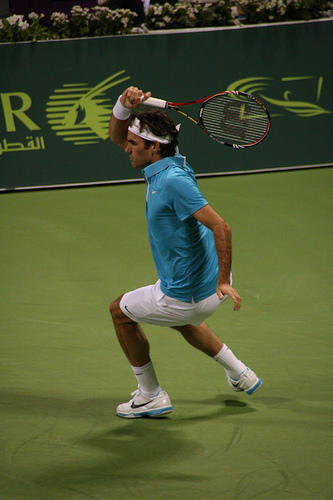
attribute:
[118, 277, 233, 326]
shorts — nike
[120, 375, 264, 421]
sneakers — black 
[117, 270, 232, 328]
shorts — White 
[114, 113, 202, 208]
man — playing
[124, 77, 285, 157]
racket — black red and white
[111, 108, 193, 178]
head — White 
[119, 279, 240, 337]
shorts — White 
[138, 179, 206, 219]
shirt — blue 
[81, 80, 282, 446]
man — wearing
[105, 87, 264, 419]
man — wearing